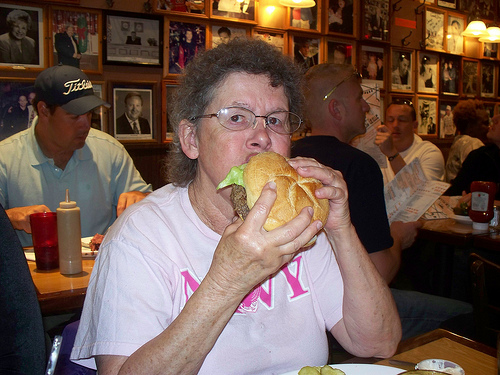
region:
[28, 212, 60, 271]
A red plastic cup.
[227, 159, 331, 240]
A large burger.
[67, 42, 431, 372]
A woman eating a burger.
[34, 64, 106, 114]
A navy blue hat with white writing.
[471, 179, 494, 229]
A red and white bottle of ketchup.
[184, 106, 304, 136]
A pair of glasses.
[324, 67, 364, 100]
A gold rimmed pair of sunglasses.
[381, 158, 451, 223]
A restaurant menu.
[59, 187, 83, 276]
A beige bottle with a pointed lid.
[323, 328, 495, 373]
A wooden table.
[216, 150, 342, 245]
giant hamburger being eaten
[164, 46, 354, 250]
woman eating a giant hamburger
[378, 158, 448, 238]
menu being looked at before ordering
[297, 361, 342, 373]
pickle chips on a plate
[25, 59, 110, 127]
navy blue baseball cap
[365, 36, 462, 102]
autographs hanging on a wall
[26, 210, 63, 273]
half-full plastic soda glass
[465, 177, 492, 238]
squeezable ketchup bottle on a table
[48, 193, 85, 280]
a condiment bottle that is squeezable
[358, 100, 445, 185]
man looking over a menu before ordering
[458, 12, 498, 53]
small yellow dish-shaped lights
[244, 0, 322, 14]
small yellow dish-shaped lights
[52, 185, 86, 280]
plastic condiment bottle on table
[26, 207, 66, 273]
dark red translucent plastic cup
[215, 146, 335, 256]
large circular hamburger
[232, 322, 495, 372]
light brown wooden table with dark brown wooden trim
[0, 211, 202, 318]
light brown wooden table with dark brown wooden trim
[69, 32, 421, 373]
person in white and pink shirt eating large hamburger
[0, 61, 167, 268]
man wearing dark blue hat eating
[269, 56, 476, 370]
man in black shirt with sunglasses on his head reading a menu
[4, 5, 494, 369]
people sitting at tables in a food establishment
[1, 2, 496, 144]
framed photographs of people crowded onto a wall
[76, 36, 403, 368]
woman holding a very large burger to her mouth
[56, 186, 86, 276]
a pale brown squeeze bottle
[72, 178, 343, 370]
woman wearing a light pink shirt with pink letters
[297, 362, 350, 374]
pickle slices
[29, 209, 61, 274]
a red plastic cup about half full of liquid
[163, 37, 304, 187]
woman's greying hair is frizzy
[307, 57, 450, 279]
man holding a menu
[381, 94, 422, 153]
glasses up high on man's head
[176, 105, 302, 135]
the glasses on the woman's face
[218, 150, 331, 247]
the big burger in the woman's hands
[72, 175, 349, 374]
the short sleeved shirt on the older woman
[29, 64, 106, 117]
the hat on the man's head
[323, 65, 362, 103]
the sunglasses on the man's head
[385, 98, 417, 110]
the sunglasses on the man's head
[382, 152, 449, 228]
the menu in the man's hand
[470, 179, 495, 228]
the ketchup bottle on the table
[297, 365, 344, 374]
the pickle slices on the plate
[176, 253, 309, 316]
the design on the front of the woman's shirt